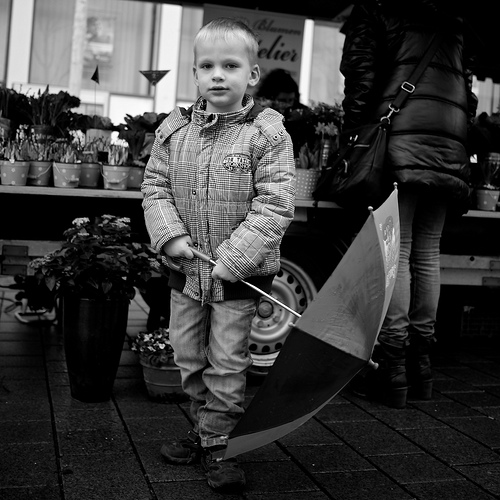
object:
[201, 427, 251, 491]
shoes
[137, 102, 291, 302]
jacket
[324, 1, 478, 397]
woman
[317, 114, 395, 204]
handbag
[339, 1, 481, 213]
jacket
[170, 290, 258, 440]
jeans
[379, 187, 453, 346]
jeans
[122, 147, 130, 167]
plants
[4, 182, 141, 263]
cart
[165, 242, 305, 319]
handle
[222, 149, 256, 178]
patch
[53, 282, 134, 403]
vase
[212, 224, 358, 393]
wheel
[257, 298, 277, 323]
lug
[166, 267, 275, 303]
trim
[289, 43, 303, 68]
words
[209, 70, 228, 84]
nose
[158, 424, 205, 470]
shoe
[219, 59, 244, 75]
eye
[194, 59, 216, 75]
eye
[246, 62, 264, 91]
ear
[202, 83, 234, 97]
mouth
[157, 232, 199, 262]
hand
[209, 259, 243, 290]
hand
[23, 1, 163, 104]
window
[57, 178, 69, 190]
pots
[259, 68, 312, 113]
lady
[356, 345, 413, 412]
boots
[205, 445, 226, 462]
velcro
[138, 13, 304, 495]
child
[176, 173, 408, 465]
umbrella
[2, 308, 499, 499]
ground